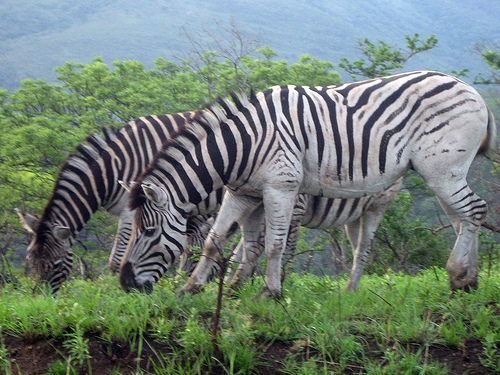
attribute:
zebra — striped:
[27, 68, 351, 309]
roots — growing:
[4, 278, 466, 356]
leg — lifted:
[425, 176, 483, 281]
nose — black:
[104, 254, 164, 305]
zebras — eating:
[24, 63, 474, 307]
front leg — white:
[176, 188, 263, 295]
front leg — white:
[260, 160, 303, 303]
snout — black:
[116, 260, 140, 295]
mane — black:
[36, 122, 121, 253]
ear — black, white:
[11, 207, 41, 235]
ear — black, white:
[50, 223, 73, 241]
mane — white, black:
[34, 120, 123, 260]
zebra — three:
[33, 59, 481, 324]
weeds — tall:
[14, 245, 479, 355]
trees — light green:
[13, 56, 483, 278]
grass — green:
[256, 267, 393, 357]